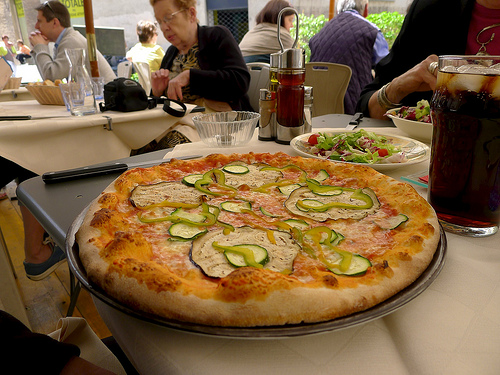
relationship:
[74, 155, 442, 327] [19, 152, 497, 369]
pizza on table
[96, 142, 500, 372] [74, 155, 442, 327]
tablecloth under pizza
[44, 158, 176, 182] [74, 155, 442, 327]
knife beside pizza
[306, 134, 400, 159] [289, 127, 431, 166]
salad in plate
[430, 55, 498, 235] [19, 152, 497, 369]
soda on table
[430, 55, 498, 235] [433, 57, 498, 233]
soda in glass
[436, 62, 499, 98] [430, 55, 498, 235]
cubes are in soda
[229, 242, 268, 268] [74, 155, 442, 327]
cucumber on pizza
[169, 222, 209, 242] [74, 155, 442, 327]
cucumber on pizza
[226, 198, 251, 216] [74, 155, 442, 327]
cucumber on pizza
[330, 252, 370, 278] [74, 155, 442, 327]
cucumber on pizza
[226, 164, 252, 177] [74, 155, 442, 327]
cucumber on pizza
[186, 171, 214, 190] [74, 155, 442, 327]
cucumber on pizza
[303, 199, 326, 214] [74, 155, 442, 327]
cucumber on pizza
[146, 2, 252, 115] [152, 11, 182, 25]
woman wearing glasses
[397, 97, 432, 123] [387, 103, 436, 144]
salad in bowl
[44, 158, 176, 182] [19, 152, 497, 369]
knife on table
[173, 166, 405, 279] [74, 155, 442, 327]
cucumbers are on pizza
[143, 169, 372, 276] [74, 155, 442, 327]
peppers are on pizza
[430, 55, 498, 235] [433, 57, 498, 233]
fluid in glass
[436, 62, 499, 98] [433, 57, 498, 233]
ice in glass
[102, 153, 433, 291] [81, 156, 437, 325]
cheese on crust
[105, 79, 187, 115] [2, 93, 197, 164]
bag on table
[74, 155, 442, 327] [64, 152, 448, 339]
pizza on plate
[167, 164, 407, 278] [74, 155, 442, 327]
vegetables are on pizza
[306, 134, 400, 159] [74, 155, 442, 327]
salad behind pizza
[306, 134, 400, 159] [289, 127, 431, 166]
salad on plate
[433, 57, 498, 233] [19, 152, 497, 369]
glass on table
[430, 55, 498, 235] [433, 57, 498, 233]
coca-cola in glass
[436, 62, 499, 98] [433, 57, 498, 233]
cubes are in glass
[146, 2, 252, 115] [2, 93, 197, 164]
woman sits at table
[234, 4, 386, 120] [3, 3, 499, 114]
people sit in background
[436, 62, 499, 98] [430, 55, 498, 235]
ice in soda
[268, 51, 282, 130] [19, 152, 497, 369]
oil on table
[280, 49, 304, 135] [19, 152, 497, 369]
vinager on table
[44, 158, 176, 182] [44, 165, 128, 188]
knife has handle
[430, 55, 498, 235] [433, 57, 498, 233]
liquid in glass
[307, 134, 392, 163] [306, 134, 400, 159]
tomatoes are on salad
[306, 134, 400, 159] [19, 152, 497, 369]
salad on table